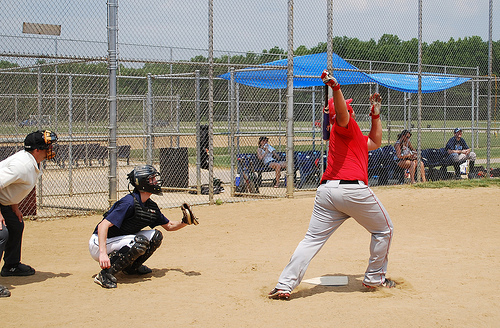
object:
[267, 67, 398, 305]
man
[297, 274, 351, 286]
plate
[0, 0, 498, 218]
fence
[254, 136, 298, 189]
people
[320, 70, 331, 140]
bat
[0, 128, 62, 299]
umpire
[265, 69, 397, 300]
body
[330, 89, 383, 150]
arms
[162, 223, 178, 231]
elbow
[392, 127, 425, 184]
woman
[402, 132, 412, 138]
sunglasses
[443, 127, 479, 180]
man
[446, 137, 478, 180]
uniform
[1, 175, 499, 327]
ground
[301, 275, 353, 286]
home base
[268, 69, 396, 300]
batter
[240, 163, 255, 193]
bat